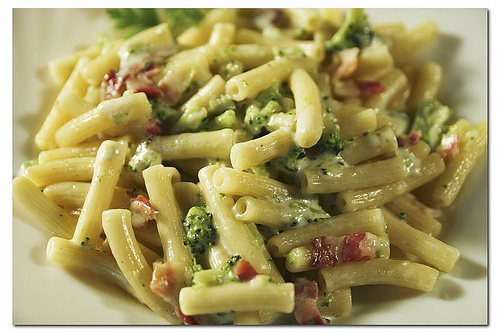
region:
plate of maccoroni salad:
[56, 45, 438, 319]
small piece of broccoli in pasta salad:
[179, 206, 213, 253]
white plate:
[19, 273, 111, 330]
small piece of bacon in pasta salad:
[311, 233, 376, 260]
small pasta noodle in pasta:
[142, 165, 184, 275]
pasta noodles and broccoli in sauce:
[216, 52, 331, 166]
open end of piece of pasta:
[226, 77, 248, 99]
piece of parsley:
[102, 8, 207, 31]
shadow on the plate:
[434, 25, 486, 101]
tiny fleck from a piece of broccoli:
[79, 231, 94, 250]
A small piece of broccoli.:
[183, 206, 213, 249]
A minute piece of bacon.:
[288, 280, 323, 325]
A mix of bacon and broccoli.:
[96, 66, 243, 151]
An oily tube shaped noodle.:
[178, 282, 298, 320]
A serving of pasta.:
[23, 13, 477, 328]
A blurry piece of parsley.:
[102, 8, 174, 34]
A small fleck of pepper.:
[316, 167, 333, 179]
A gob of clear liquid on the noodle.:
[96, 98, 127, 117]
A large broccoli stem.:
[416, 90, 449, 145]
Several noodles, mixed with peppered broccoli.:
[166, 41, 326, 178]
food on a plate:
[28, 29, 457, 277]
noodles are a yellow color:
[186, 163, 307, 218]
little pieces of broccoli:
[163, 73, 350, 259]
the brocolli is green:
[179, 85, 306, 152]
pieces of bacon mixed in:
[294, 217, 420, 284]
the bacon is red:
[300, 220, 444, 314]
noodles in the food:
[39, 82, 302, 292]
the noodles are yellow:
[39, 60, 230, 267]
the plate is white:
[22, 14, 119, 122]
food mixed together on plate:
[46, 15, 413, 285]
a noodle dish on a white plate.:
[18, 5, 464, 320]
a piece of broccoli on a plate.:
[172, 203, 217, 251]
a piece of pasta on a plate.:
[175, 278, 301, 320]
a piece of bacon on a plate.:
[144, 260, 184, 302]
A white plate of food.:
[16, 5, 487, 325]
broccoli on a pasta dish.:
[183, 193, 273, 279]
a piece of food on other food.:
[318, 235, 378, 260]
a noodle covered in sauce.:
[86, 140, 154, 241]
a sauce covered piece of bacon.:
[139, 265, 181, 307]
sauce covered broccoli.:
[241, 103, 291, 129]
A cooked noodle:
[290, 69, 321, 147]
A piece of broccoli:
[182, 206, 214, 251]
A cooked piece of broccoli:
[182, 206, 214, 250]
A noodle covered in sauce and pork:
[286, 234, 381, 268]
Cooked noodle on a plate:
[181, 280, 293, 312]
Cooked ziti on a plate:
[21, 12, 471, 314]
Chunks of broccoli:
[183, 102, 277, 128]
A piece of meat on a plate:
[436, 135, 460, 155]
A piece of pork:
[100, 68, 130, 96]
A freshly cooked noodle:
[212, 169, 302, 196]